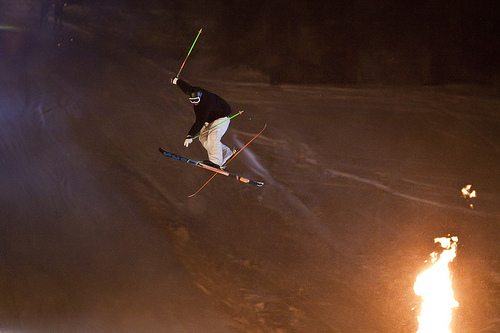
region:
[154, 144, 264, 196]
the long ski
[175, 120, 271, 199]
the long red ski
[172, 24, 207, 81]
the green and orange ski pole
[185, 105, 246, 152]
the green and orange ski pole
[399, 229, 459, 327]
the large orange fire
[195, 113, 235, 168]
the tan pants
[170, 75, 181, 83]
the white glove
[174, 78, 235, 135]
the black long sleeved shirt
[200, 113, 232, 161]
the leg of the man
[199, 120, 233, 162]
the long leg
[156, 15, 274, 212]
skier has jumped into the air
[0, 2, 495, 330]
this picture is night time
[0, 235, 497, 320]
snow appears orange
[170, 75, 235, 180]
person wearing ski goggles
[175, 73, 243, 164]
person wearing white pants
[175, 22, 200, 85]
ski pole is red and green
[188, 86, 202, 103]
the head of the snowboarder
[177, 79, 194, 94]
the arm of of the snowboarder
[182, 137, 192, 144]
the hand of the snowboarder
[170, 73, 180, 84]
the hand of the snowboarder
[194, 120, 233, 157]
the leg of the snowboarder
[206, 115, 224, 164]
the leg of the snowboarder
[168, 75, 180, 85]
the white glove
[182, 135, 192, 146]
the white glove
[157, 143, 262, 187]
the blue orange and black ski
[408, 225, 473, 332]
Small line of burning flame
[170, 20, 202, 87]
Red and green ski pole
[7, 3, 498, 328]
Snow slope covered with snow at night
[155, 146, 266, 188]
Pair of skis with blue writing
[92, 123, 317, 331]
Line of tracks in the snow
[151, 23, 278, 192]
Skier in black jacket and white pants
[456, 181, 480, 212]
Small bit of flame in air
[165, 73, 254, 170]
Man wearing goggles and white gloves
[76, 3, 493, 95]
Line of trees and snow at night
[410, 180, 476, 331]
a pillar of fire against the snow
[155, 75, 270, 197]
skier floating through midair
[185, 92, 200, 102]
skier wearing dark goggles on his head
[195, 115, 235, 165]
skier is wearing baggy snow pants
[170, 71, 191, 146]
skier is wearing white gloves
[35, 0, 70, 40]
two people standing on an icy hill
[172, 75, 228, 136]
skier is wearing a black sweater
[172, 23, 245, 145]
skier's ski poles are kelly green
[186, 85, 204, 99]
skier is wearing a protective black helmet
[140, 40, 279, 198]
skier doing trick at night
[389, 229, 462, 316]
flame from fire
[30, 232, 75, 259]
tracks in white snow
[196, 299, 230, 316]
tracks in white snow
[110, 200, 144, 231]
tracks in white snow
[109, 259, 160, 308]
tracks in white snow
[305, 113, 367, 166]
tracks in white snow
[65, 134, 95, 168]
tracks in white snow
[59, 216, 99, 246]
tracks in white snow